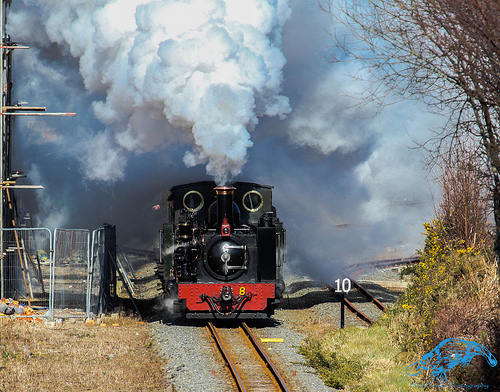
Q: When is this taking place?
A: Daytime.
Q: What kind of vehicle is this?
A: Train.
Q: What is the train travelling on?
A: Train tracks.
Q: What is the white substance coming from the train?
A: Smoke.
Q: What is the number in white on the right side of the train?
A: 10.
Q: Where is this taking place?
A: At a train exhibit.